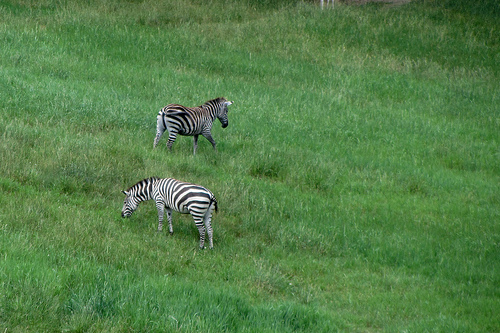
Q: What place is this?
A: It is a field.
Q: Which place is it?
A: It is a field.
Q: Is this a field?
A: Yes, it is a field.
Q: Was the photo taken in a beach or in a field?
A: It was taken at a field.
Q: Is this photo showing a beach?
A: No, the picture is showing a field.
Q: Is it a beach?
A: No, it is a field.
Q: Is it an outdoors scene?
A: Yes, it is outdoors.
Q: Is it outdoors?
A: Yes, it is outdoors.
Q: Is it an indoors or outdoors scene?
A: It is outdoors.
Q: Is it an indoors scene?
A: No, it is outdoors.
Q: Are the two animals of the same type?
A: Yes, all the animals are zebras.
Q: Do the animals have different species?
A: No, all the animals are zebras.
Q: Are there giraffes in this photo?
A: No, there are no giraffes.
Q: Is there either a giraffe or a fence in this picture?
A: No, there are no giraffes or fences.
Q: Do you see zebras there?
A: Yes, there is a zebra.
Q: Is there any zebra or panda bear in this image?
A: Yes, there is a zebra.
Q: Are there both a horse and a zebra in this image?
A: No, there is a zebra but no horses.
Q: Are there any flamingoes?
A: No, there are no flamingoes.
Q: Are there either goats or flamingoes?
A: No, there are no flamingoes or goats.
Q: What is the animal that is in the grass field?
A: The animal is a zebra.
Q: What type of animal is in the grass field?
A: The animal is a zebra.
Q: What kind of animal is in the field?
A: The animal is a zebra.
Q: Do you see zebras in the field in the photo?
A: Yes, there is a zebra in the field.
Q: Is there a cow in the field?
A: No, there is a zebra in the field.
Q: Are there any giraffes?
A: No, there are no giraffes.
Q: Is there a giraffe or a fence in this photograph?
A: No, there are no giraffes or fences.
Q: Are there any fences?
A: No, there are no fences.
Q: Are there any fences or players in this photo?
A: No, there are no fences or players.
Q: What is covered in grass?
A: The field is covered in grass.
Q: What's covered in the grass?
A: The field is covered in grass.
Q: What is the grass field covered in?
A: The field is covered in grass.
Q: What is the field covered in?
A: The field is covered in grass.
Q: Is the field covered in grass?
A: Yes, the field is covered in grass.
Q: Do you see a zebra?
A: Yes, there is a zebra.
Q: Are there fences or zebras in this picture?
A: Yes, there is a zebra.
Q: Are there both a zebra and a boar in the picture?
A: No, there is a zebra but no boars.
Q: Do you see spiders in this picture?
A: No, there are no spiders.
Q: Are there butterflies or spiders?
A: No, there are no spiders or butterflies.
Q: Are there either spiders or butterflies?
A: No, there are no spiders or butterflies.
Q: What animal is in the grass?
A: The animal is a zebra.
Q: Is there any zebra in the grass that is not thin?
A: Yes, there is a zebra in the grass.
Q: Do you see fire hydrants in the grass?
A: No, there is a zebra in the grass.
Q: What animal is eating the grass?
A: The zebra is eating the grass.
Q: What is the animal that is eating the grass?
A: The animal is a zebra.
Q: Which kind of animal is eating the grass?
A: The animal is a zebra.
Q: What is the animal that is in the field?
A: The animal is a zebra.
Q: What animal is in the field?
A: The animal is a zebra.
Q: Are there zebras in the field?
A: Yes, there is a zebra in the field.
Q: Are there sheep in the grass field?
A: No, there is a zebra in the field.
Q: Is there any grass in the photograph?
A: Yes, there is grass.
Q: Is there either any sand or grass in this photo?
A: Yes, there is grass.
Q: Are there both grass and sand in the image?
A: No, there is grass but no sand.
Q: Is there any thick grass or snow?
A: Yes, there is thick grass.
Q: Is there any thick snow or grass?
A: Yes, there is thick grass.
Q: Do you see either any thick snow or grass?
A: Yes, there is thick grass.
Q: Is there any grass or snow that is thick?
A: Yes, the grass is thick.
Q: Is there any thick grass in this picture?
A: Yes, there is thick grass.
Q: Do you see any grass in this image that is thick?
A: Yes, there is thick grass.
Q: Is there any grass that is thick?
A: Yes, there is grass that is thick.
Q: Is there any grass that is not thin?
A: Yes, there is thick grass.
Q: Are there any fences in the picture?
A: No, there are no fences.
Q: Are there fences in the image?
A: No, there are no fences.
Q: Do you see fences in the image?
A: No, there are no fences.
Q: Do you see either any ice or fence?
A: No, there are no fences or ice.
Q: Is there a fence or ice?
A: No, there are no fences or ice.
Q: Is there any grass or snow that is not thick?
A: No, there is grass but it is thick.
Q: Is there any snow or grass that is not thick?
A: No, there is grass but it is thick.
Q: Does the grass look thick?
A: Yes, the grass is thick.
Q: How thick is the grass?
A: The grass is thick.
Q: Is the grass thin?
A: No, the grass is thick.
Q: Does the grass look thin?
A: No, the grass is thick.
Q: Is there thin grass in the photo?
A: No, there is grass but it is thick.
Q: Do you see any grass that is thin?
A: No, there is grass but it is thick.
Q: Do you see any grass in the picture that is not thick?
A: No, there is grass but it is thick.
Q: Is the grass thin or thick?
A: The grass is thick.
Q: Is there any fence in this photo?
A: No, there are no fences.